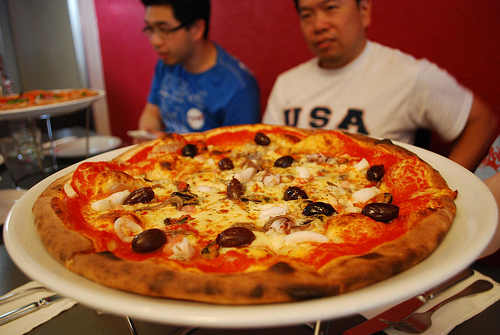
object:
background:
[0, 0, 497, 334]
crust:
[33, 175, 459, 305]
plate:
[43, 134, 122, 159]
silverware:
[337, 267, 474, 334]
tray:
[0, 123, 499, 329]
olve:
[282, 186, 310, 199]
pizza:
[33, 124, 457, 306]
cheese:
[195, 200, 237, 225]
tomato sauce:
[309, 225, 405, 270]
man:
[254, 1, 499, 178]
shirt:
[260, 38, 479, 150]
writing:
[335, 105, 370, 134]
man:
[126, 0, 263, 146]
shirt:
[143, 40, 265, 132]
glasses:
[139, 21, 196, 39]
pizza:
[0, 88, 105, 117]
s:
[306, 105, 332, 130]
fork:
[376, 278, 491, 334]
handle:
[427, 276, 493, 313]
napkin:
[358, 270, 500, 335]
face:
[294, 2, 359, 63]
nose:
[310, 13, 330, 36]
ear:
[357, 0, 373, 28]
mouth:
[310, 36, 339, 54]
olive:
[274, 154, 298, 169]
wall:
[93, 0, 500, 159]